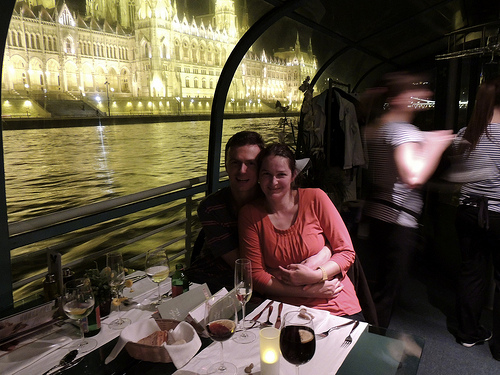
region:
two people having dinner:
[185, 115, 396, 318]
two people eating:
[200, 129, 377, 313]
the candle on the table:
[258, 317, 290, 374]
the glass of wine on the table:
[275, 307, 322, 371]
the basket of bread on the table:
[104, 312, 210, 374]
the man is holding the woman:
[196, 110, 388, 317]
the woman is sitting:
[243, 146, 376, 315]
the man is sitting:
[174, 122, 285, 282]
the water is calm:
[11, 132, 186, 177]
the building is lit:
[6, 33, 323, 119]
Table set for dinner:
[18, 243, 345, 373]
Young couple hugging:
[198, 124, 350, 302]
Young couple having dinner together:
[51, 126, 375, 374]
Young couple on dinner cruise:
[6, 6, 407, 373]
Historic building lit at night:
[0, 1, 326, 118]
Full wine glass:
[278, 311, 319, 371]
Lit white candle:
[253, 323, 282, 372]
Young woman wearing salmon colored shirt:
[243, 141, 360, 316]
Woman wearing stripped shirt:
[440, 67, 497, 352]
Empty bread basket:
[102, 313, 203, 370]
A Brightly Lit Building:
[16, 0, 198, 96]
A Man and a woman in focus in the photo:
[178, 125, 361, 293]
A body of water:
[18, 132, 170, 186]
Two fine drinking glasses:
[207, 246, 251, 369]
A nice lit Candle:
[253, 327, 290, 373]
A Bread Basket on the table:
[121, 315, 190, 372]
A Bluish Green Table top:
[378, 325, 419, 371]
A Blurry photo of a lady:
[359, 70, 447, 326]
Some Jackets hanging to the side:
[309, 86, 363, 193]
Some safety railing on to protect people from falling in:
[0, 177, 209, 267]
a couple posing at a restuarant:
[211, 112, 356, 307]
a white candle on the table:
[250, 319, 282, 369]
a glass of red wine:
[284, 308, 315, 368]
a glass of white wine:
[137, 244, 177, 295]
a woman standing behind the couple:
[387, 70, 449, 265]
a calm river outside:
[11, 129, 173, 184]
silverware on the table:
[324, 319, 357, 348]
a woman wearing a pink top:
[247, 145, 345, 285]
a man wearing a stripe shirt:
[197, 140, 257, 251]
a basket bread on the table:
[129, 308, 207, 363]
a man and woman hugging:
[193, 128, 359, 312]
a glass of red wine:
[200, 296, 236, 374]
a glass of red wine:
[230, 255, 256, 346]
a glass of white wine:
[60, 279, 95, 353]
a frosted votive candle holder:
[255, 326, 281, 374]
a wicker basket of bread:
[114, 317, 196, 365]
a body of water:
[5, 113, 312, 294]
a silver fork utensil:
[339, 317, 365, 351]